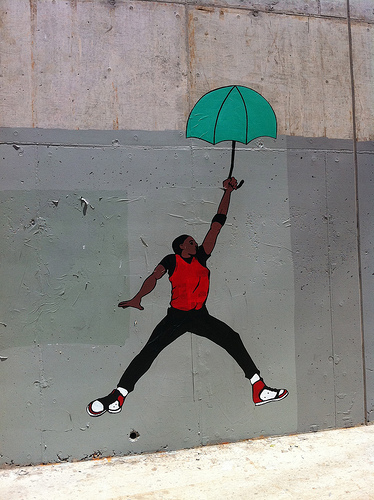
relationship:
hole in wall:
[129, 430, 139, 442] [6, 14, 362, 490]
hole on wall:
[129, 430, 139, 442] [20, 225, 109, 382]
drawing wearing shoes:
[81, 79, 301, 418] [80, 376, 290, 419]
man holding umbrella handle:
[86, 176, 289, 419] [227, 163, 246, 191]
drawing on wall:
[81, 79, 301, 418] [3, 0, 355, 426]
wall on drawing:
[3, 0, 355, 426] [81, 79, 301, 418]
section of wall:
[12, 291, 116, 359] [3, 0, 355, 426]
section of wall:
[82, 165, 183, 221] [3, 0, 355, 426]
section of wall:
[256, 282, 290, 328] [3, 0, 355, 426]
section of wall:
[251, 300, 297, 336] [3, 0, 355, 426]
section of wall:
[247, 279, 358, 372] [15, 186, 361, 402]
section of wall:
[3, 236, 296, 424] [6, 342, 141, 448]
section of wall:
[14, 230, 121, 345] [8, 155, 352, 410]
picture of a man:
[3, 137, 355, 431] [87, 182, 308, 421]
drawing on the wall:
[81, 79, 301, 418] [6, 14, 362, 490]